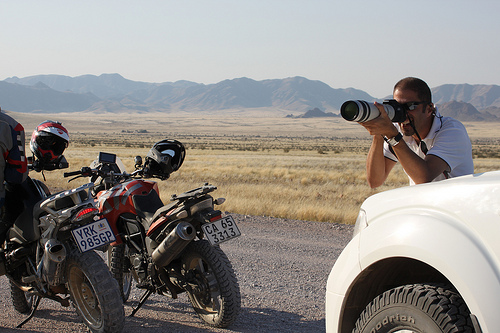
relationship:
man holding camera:
[332, 69, 478, 189] [335, 94, 410, 131]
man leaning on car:
[332, 69, 478, 189] [318, 165, 499, 331]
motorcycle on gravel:
[61, 146, 247, 333] [0, 211, 360, 333]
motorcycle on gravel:
[2, 149, 135, 332] [0, 211, 360, 333]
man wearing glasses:
[332, 69, 478, 189] [394, 94, 433, 113]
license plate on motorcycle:
[198, 211, 245, 251] [61, 146, 247, 333]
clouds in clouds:
[1, 1, 500, 98] [1, 1, 500, 73]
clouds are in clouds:
[1, 1, 500, 98] [1, 1, 500, 73]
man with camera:
[332, 69, 478, 189] [335, 94, 410, 131]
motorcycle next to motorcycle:
[61, 146, 247, 333] [2, 149, 135, 332]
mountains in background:
[1, 65, 498, 125] [2, 1, 498, 149]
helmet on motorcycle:
[27, 117, 74, 168] [2, 149, 135, 332]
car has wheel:
[318, 165, 499, 331] [345, 279, 483, 333]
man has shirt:
[332, 69, 478, 189] [379, 100, 479, 188]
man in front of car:
[332, 69, 478, 189] [318, 165, 499, 331]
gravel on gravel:
[6, 211, 360, 333] [0, 211, 360, 333]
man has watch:
[332, 69, 478, 189] [385, 127, 405, 152]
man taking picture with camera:
[332, 69, 478, 189] [335, 94, 410, 131]